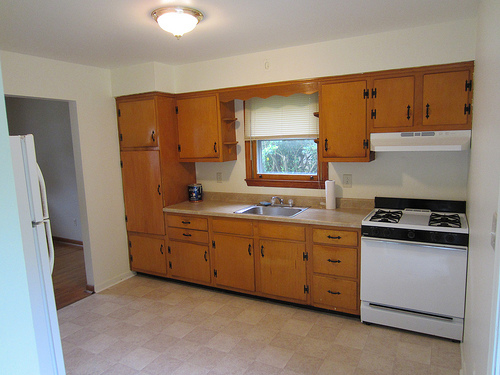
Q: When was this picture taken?
A: Daytime.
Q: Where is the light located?
A: Ceiling.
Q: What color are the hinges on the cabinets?
A: Black.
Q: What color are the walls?
A: White.